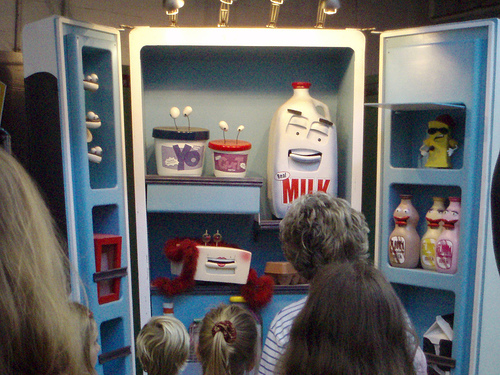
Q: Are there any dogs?
A: No, there are no dogs.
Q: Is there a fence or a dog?
A: No, there are no dogs or fences.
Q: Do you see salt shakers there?
A: No, there are no salt shakers.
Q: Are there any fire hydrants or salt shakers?
A: No, there are no salt shakers or fire hydrants.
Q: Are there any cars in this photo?
A: No, there are no cars.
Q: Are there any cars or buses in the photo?
A: No, there are no cars or buses.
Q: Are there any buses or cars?
A: No, there are no cars or buses.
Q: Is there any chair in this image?
A: No, there are no chairs.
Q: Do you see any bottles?
A: Yes, there is a bottle.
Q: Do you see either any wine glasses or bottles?
A: Yes, there is a bottle.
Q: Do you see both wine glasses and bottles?
A: No, there is a bottle but no wine glasses.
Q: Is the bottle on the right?
A: Yes, the bottle is on the right of the image.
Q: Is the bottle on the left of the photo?
A: No, the bottle is on the right of the image.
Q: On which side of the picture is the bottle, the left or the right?
A: The bottle is on the right of the image.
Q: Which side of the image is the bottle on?
A: The bottle is on the right of the image.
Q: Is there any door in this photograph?
A: Yes, there is a door.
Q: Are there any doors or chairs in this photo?
A: Yes, there is a door.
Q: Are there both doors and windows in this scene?
A: No, there is a door but no windows.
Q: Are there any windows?
A: No, there are no windows.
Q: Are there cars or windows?
A: No, there are no windows or cars.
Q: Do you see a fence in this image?
A: No, there are no fences.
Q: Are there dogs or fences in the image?
A: No, there are no fences or dogs.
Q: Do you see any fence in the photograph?
A: No, there are no fences.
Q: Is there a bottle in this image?
A: Yes, there is a bottle.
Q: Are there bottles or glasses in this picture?
A: Yes, there is a bottle.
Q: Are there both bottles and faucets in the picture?
A: No, there is a bottle but no faucets.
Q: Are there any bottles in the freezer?
A: Yes, there is a bottle in the freezer.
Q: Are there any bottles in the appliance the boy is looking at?
A: Yes, there is a bottle in the freezer.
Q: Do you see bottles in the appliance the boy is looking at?
A: Yes, there is a bottle in the freezer.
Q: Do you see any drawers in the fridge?
A: No, there is a bottle in the fridge.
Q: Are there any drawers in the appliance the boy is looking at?
A: No, there is a bottle in the fridge.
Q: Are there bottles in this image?
A: Yes, there is a bottle.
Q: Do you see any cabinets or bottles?
A: Yes, there is a bottle.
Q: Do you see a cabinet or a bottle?
A: Yes, there is a bottle.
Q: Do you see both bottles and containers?
A: Yes, there are both a bottle and a container.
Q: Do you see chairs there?
A: No, there are no chairs.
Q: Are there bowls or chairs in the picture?
A: No, there are no chairs or bowls.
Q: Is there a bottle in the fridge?
A: Yes, there is a bottle in the fridge.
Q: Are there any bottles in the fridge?
A: Yes, there is a bottle in the fridge.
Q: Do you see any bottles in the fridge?
A: Yes, there is a bottle in the fridge.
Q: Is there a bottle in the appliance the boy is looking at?
A: Yes, there is a bottle in the fridge.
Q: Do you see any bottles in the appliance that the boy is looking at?
A: Yes, there is a bottle in the fridge.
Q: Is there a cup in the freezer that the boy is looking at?
A: No, there is a bottle in the fridge.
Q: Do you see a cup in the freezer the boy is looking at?
A: No, there is a bottle in the fridge.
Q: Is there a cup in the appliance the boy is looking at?
A: No, there is a bottle in the fridge.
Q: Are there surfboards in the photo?
A: No, there are no surfboards.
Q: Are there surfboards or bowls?
A: No, there are no surfboards or bowls.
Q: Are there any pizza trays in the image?
A: No, there are no pizza trays.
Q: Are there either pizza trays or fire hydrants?
A: No, there are no pizza trays or fire hydrants.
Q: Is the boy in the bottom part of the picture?
A: Yes, the boy is in the bottom of the image.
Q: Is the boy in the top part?
A: No, the boy is in the bottom of the image.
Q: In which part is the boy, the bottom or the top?
A: The boy is in the bottom of the image.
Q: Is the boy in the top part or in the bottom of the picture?
A: The boy is in the bottom of the image.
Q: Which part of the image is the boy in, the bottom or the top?
A: The boy is in the bottom of the image.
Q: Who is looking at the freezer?
A: The boy is looking at the freezer.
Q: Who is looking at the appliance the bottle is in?
A: The boy is looking at the freezer.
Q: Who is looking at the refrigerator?
A: The boy is looking at the freezer.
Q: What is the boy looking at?
A: The boy is looking at the fridge.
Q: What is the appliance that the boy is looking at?
A: The appliance is a refrigerator.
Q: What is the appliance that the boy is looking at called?
A: The appliance is a refrigerator.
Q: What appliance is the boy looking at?
A: The boy is looking at the freezer.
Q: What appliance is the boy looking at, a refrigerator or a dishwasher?
A: The boy is looking at a refrigerator.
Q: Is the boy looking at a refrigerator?
A: Yes, the boy is looking at a refrigerator.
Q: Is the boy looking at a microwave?
A: No, the boy is looking at a refrigerator.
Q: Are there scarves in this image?
A: Yes, there is a scarf.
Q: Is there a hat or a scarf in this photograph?
A: Yes, there is a scarf.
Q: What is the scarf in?
A: The scarf is in the freezer.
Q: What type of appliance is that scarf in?
A: The scarf is in the freezer.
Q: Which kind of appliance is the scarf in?
A: The scarf is in the freezer.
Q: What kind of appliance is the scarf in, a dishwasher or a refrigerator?
A: The scarf is in a refrigerator.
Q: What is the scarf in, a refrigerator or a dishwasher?
A: The scarf is in a refrigerator.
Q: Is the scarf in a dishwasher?
A: No, the scarf is in the freezer.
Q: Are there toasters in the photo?
A: Yes, there is a toaster.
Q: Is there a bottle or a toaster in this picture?
A: Yes, there is a toaster.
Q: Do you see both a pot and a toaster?
A: No, there is a toaster but no pots.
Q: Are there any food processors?
A: No, there are no food processors.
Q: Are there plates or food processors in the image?
A: No, there are no food processors or plates.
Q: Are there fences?
A: No, there are no fences.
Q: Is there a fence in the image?
A: No, there are no fences.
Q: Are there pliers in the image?
A: No, there are no pliers.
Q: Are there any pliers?
A: No, there are no pliers.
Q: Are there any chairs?
A: No, there are no chairs.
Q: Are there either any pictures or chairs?
A: No, there are no chairs or pictures.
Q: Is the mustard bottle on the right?
A: Yes, the mustard bottle is on the right of the image.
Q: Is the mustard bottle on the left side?
A: No, the mustard bottle is on the right of the image.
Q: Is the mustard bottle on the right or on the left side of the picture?
A: The mustard bottle is on the right of the image.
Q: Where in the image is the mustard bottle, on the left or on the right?
A: The mustard bottle is on the right of the image.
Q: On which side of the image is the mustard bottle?
A: The mustard bottle is on the right of the image.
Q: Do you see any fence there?
A: No, there are no fences.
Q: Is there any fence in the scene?
A: No, there are no fences.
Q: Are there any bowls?
A: No, there are no bowls.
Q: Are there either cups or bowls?
A: No, there are no bowls or cups.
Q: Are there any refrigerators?
A: Yes, there is a refrigerator.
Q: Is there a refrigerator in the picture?
A: Yes, there is a refrigerator.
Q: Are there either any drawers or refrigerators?
A: Yes, there is a refrigerator.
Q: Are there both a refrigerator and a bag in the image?
A: No, there is a refrigerator but no bags.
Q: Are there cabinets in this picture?
A: No, there are no cabinets.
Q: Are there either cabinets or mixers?
A: No, there are no cabinets or mixers.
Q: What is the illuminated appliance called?
A: The appliance is a refrigerator.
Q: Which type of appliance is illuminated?
A: The appliance is a refrigerator.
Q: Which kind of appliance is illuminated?
A: The appliance is a refrigerator.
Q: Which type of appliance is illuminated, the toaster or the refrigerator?
A: The refrigerator is illuminated.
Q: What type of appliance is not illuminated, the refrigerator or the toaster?
A: The toaster is not illuminated.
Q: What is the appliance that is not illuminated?
A: The appliance is a toaster.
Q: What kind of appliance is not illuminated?
A: The appliance is a toaster.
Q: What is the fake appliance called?
A: The appliance is a refrigerator.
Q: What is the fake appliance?
A: The appliance is a refrigerator.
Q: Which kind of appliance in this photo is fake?
A: The appliance is a refrigerator.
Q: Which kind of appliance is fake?
A: The appliance is a refrigerator.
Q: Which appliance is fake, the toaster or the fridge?
A: The fridge is fake.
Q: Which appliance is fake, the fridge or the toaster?
A: The fridge is fake.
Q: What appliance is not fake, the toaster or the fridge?
A: The toaster is not fake.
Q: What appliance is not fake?
A: The appliance is a toaster.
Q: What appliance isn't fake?
A: The appliance is a toaster.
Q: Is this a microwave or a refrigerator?
A: This is a refrigerator.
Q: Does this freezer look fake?
A: Yes, the freezer is fake.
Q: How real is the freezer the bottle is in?
A: The refrigerator is fake.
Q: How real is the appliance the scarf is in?
A: The refrigerator is fake.